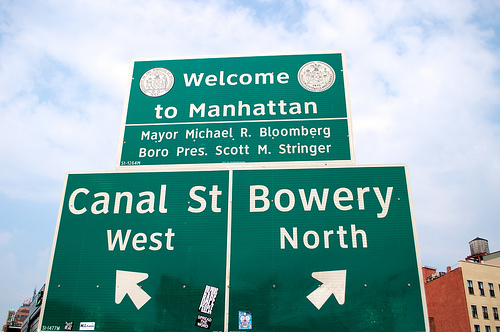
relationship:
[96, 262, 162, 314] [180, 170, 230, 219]
arrow points to street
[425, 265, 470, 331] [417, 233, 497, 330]
brick brick building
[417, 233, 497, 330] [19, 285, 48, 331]
building by train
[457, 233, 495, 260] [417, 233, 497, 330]
tower above building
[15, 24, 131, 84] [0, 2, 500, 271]
clouds in sky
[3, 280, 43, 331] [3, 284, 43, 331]
buildings in buildings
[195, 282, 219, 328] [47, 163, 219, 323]
black on sign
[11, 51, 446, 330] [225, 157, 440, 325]
three green sign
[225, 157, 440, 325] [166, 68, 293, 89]
sign have letters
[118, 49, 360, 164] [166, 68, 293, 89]
sign has letters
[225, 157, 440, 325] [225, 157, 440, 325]
sign on sign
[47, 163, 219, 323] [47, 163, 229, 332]
sign on sign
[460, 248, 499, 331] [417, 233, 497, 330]
tan red building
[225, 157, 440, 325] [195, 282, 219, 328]
sign have black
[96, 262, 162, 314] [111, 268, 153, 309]
arrow points arrow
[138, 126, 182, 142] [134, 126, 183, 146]
letters read mayor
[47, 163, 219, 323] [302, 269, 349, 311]
sign with arrow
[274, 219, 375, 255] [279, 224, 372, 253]
north in lettering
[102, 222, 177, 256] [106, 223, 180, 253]
west in lettering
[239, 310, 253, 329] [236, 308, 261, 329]
figure of figure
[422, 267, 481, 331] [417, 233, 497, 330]
brick complex building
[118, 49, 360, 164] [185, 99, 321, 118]
sign to manhattan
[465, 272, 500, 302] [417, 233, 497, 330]
windows on building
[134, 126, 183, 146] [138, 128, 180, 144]
mayor in lettering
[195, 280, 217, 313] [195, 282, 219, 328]
black white black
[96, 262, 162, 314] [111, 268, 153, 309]
arrow pointing arrow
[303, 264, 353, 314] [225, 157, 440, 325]
arrow pointing sign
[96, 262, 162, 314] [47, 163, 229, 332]
arrow pointing sign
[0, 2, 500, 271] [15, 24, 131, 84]
sky with clouds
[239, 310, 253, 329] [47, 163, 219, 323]
figure on sign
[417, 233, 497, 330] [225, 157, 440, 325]
building on sign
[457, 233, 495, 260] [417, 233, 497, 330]
tower on building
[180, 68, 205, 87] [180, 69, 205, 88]
letter white w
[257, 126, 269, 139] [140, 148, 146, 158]
white letter b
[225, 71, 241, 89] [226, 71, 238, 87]
white letter c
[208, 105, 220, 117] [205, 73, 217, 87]
white letter e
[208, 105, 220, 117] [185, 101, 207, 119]
white letter m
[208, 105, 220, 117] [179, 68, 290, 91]
white word welcome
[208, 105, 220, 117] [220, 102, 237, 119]
white letter n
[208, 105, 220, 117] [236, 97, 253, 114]
white letter h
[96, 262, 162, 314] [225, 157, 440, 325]
arrow pointing sign